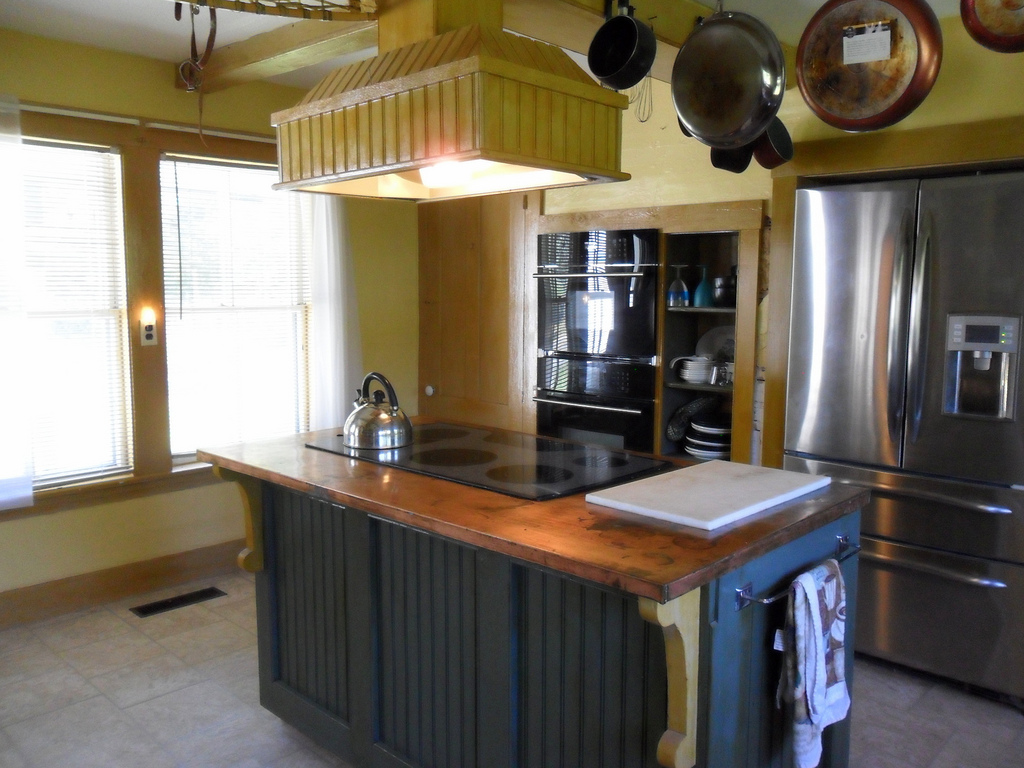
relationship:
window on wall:
[2, 142, 138, 485] [4, 0, 1017, 611]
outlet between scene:
[122, 285, 165, 356] [0, 126, 332, 488]